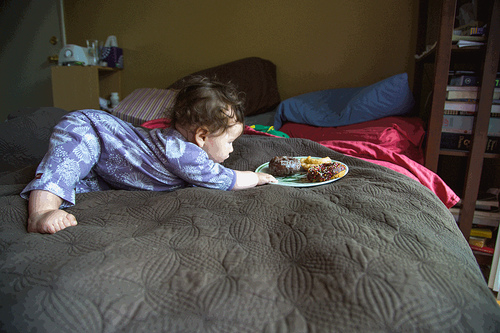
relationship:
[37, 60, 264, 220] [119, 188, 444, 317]
baby on bed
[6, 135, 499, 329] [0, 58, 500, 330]
bedspread on bed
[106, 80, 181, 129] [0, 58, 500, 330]
pillow on bed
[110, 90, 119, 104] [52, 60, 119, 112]
medicine on shelf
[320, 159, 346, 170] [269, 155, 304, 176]
sprinkles on donut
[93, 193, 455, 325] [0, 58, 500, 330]
blanket on bed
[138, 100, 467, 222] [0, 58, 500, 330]
sheet on bed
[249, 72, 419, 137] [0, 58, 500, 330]
pillow on bed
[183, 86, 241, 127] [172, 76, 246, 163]
hair on head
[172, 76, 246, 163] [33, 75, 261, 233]
head of baby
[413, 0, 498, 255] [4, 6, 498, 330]
book shelf in bedroom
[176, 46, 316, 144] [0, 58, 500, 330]
pillow on bed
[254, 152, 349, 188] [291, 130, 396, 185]
plate under food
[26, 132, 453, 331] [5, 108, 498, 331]
design on blanket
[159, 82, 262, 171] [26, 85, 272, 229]
head of kid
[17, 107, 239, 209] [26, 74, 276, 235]
outfit on baby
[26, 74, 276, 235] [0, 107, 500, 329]
baby on bed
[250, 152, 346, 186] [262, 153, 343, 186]
plate has food